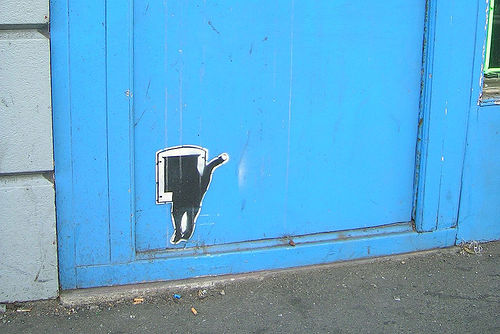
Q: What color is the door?
A: Blue.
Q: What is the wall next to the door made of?
A: Cement.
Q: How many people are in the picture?
A: No people.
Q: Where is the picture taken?
A: Outside a door.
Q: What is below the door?
A: Concrete.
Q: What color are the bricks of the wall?
A: Gray.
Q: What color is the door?
A: Blue.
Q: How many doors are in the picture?
A: One.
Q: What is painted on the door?
A: Cat going through cat door.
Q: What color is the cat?
A: Black.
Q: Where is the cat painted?
A: On the bottom left of the door.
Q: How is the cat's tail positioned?
A: Bent.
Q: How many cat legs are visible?
A: Two.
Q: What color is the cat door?
A: White.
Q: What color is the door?
A: Blue.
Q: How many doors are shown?
A: One.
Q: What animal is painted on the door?
A: A cat.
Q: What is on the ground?
A: Pebbles.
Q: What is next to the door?
A: A wall.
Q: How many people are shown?
A: Zero.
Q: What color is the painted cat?
A: Black.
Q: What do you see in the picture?
A: A door.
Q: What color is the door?
A: Blue.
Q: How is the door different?
A: It has a cat door painted on it.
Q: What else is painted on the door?
A: The back end of a cat going in the cat door.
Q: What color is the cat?
A: Black.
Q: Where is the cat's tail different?
A: It has a white tip.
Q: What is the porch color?
A: Gray.